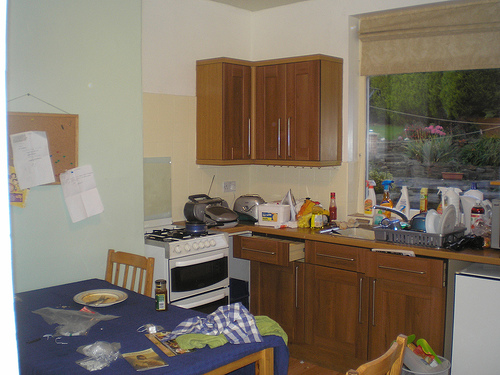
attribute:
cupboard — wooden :
[254, 253, 304, 348]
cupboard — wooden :
[209, 216, 309, 262]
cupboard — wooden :
[300, 229, 375, 272]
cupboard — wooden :
[286, 249, 368, 373]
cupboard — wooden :
[369, 242, 448, 291]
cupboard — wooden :
[363, 254, 442, 373]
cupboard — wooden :
[213, 60, 262, 171]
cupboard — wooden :
[235, 55, 311, 169]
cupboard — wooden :
[264, 52, 327, 166]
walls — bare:
[82, 52, 184, 158]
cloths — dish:
[148, 305, 294, 357]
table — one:
[41, 278, 288, 370]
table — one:
[17, 270, 283, 373]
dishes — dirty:
[41, 262, 146, 371]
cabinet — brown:
[189, 51, 349, 168]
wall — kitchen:
[142, 47, 195, 160]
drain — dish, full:
[368, 185, 469, 254]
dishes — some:
[369, 189, 483, 246]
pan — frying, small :
[152, 216, 234, 242]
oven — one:
[147, 208, 232, 303]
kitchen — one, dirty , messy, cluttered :
[22, 13, 498, 364]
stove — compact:
[147, 219, 239, 321]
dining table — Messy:
[17, 275, 288, 374]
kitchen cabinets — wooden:
[230, 227, 445, 367]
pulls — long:
[358, 276, 376, 326]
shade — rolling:
[358, 4, 498, 74]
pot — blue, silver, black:
[183, 216, 223, 236]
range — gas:
[144, 216, 231, 316]